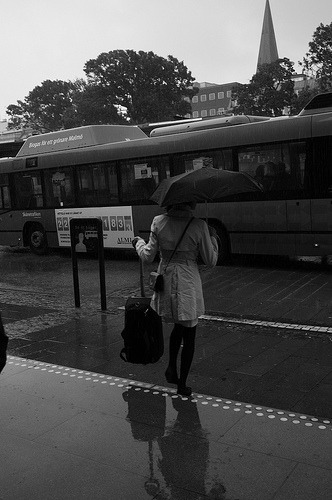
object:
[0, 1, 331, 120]
sky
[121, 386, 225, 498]
shadow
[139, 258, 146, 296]
handle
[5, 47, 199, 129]
tree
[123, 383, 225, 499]
reflection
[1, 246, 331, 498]
ground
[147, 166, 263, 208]
umbrella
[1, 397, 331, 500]
raining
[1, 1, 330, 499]
photo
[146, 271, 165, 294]
purse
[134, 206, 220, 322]
coat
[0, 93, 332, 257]
bus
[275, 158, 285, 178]
passenger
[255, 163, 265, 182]
passenger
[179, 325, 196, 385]
stocking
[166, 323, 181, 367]
stocking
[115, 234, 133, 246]
writing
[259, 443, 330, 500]
black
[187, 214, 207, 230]
shoulder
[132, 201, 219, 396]
woman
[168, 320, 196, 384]
leggins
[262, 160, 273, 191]
people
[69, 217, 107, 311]
sign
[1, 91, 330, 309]
bus-stop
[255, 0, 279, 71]
steeple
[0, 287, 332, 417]
street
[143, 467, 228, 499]
edge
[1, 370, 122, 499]
part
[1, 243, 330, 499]
floor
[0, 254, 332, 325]
road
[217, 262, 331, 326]
edge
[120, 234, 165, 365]
carry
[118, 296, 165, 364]
luggage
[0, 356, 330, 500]
plaza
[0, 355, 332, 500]
sidewalk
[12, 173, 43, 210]
window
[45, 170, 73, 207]
window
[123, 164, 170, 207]
window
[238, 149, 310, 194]
window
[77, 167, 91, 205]
window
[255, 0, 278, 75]
pyramidal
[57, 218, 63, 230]
number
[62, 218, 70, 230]
number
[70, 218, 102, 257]
advertising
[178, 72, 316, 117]
building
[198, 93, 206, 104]
window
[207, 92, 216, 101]
window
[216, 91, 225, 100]
window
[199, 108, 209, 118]
window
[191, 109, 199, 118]
window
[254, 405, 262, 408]
white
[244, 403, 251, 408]
stones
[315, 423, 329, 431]
stone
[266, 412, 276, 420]
stone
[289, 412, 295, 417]
stone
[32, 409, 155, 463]
stone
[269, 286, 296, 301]
tiles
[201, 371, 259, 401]
tile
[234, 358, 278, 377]
tile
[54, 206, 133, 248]
sign